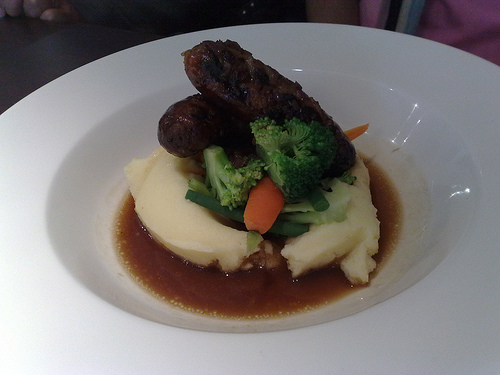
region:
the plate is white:
[278, 326, 299, 344]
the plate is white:
[365, 346, 395, 372]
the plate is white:
[381, 316, 409, 366]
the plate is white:
[330, 313, 364, 370]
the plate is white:
[352, 291, 374, 363]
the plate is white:
[386, 290, 414, 367]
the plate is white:
[334, 353, 344, 359]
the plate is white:
[369, 313, 383, 373]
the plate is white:
[353, 323, 381, 361]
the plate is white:
[341, 326, 365, 351]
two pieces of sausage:
[158, 40, 355, 174]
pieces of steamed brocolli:
[190, 117, 335, 208]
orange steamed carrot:
[245, 185, 278, 232]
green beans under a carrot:
[183, 177, 327, 238]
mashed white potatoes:
[122, 147, 379, 284]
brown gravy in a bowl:
[110, 150, 408, 320]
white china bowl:
[2, 20, 491, 374]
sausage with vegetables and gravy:
[112, 40, 404, 321]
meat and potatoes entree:
[110, 40, 402, 325]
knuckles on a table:
[0, 0, 72, 21]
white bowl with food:
[24, 24, 467, 351]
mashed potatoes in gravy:
[143, 205, 255, 269]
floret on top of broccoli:
[282, 132, 332, 195]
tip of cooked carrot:
[344, 117, 379, 142]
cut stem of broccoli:
[199, 140, 230, 177]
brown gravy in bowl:
[148, 263, 241, 315]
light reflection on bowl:
[394, 94, 427, 156]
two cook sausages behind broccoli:
[158, 35, 302, 157]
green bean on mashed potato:
[185, 186, 312, 236]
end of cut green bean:
[308, 191, 338, 218]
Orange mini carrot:
[247, 183, 279, 229]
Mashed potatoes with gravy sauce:
[130, 150, 235, 270]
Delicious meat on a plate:
[175, 40, 275, 131]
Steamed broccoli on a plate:
[252, 125, 343, 190]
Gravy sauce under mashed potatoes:
[146, 256, 328, 326]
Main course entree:
[70, 31, 455, 328]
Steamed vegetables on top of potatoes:
[201, 120, 346, 227]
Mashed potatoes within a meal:
[301, 165, 396, 287]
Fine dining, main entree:
[50, 10, 485, 355]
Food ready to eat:
[166, 32, 374, 183]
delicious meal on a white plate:
[136, 32, 475, 317]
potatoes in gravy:
[136, 153, 373, 270]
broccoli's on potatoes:
[162, 55, 344, 225]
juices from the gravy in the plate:
[125, 205, 353, 332]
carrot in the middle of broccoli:
[184, 132, 371, 253]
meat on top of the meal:
[172, 27, 306, 138]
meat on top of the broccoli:
[137, 40, 351, 197]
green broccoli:
[212, 132, 347, 226]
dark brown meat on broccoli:
[144, 27, 311, 154]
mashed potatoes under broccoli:
[106, 166, 381, 301]